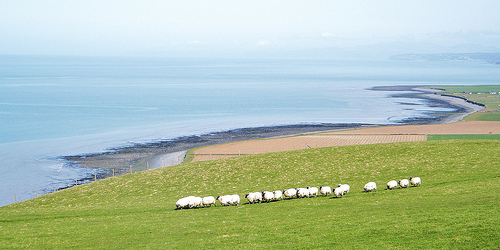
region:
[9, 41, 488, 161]
blue ocean water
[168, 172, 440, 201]
sheep in a line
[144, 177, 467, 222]
sheep grazing in grass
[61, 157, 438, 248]
grassy field beside ocean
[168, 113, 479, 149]
sandy shore against ocean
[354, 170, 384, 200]
one fluffy white sheep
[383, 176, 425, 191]
three fluffy white sheep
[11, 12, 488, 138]
blue sky that fades into ocean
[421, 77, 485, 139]
strip of sand between ocean and grass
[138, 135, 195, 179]
small pool of water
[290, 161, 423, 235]
animals on the field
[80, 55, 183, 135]
water next to the animals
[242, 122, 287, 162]
land right next to water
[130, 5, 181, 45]
sky above the water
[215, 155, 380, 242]
animals in a row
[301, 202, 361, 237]
grass next to the animals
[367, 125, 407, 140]
brown land next to grass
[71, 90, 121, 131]
water next to land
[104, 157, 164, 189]
fence next to the animals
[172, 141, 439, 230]
many animals in a group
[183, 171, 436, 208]
a line of sheep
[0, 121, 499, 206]
a fence on the landscape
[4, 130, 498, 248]
a large, grassy landscape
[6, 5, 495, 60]
a clear, blue sky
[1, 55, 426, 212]
a large body of water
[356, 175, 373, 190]
a sheep eating some grass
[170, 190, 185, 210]
a sheep eating some grass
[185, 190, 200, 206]
a sheep eating some grass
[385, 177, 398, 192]
a sheep eating some grass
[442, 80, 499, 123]
a large, grassy landscape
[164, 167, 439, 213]
sheep walking in line formation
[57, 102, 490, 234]
large green farm field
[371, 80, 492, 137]
beach side ocean shore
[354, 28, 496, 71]
mountains covered clouds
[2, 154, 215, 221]
wired fence with wood poles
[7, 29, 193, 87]
sky and ocean horizon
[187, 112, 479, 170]
brown land touching water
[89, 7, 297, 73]
white and blue cloudy sky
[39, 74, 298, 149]
calm ocean shore line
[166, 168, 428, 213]
white sheep with black heads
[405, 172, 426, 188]
sheep in a field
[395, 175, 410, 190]
sheep in a field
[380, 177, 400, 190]
sheep in a field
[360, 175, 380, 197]
sheep in a field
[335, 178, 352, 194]
sheep in a field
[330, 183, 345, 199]
sheep in a field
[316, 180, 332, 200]
sheep in a field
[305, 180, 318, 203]
sheep in a field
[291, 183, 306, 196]
sheep in a field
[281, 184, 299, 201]
sheep in a field